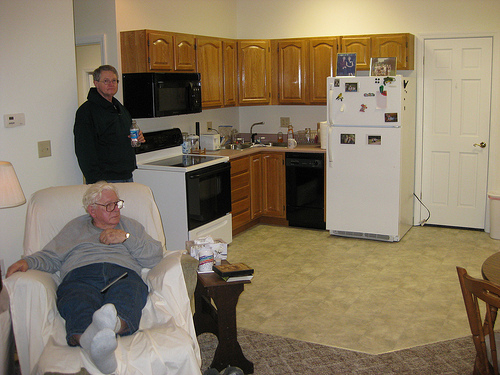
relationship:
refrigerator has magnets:
[322, 73, 416, 244] [332, 77, 402, 148]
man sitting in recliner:
[6, 181, 167, 372] [2, 181, 204, 375]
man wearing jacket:
[70, 63, 146, 180] [73, 86, 140, 181]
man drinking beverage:
[70, 63, 146, 180] [129, 119, 141, 150]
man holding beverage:
[70, 63, 146, 180] [129, 119, 141, 150]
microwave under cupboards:
[123, 72, 203, 122] [117, 30, 413, 112]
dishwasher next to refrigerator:
[281, 150, 328, 232] [322, 73, 416, 244]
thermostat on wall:
[2, 109, 28, 128] [2, 1, 84, 276]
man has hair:
[6, 181, 167, 372] [82, 181, 119, 210]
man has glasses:
[6, 181, 167, 372] [90, 200, 124, 211]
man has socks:
[6, 181, 167, 372] [74, 303, 125, 374]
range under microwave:
[133, 127, 233, 258] [123, 72, 203, 122]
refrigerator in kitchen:
[322, 73, 416, 244] [116, 2, 499, 358]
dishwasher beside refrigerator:
[281, 150, 328, 232] [322, 73, 416, 244]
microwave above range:
[123, 72, 203, 122] [133, 127, 233, 258]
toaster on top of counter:
[201, 130, 222, 154] [192, 134, 326, 156]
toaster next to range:
[201, 130, 222, 154] [133, 127, 233, 258]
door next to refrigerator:
[417, 29, 495, 232] [322, 73, 416, 244]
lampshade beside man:
[0, 158, 28, 213] [6, 181, 167, 372]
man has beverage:
[6, 181, 167, 372] [129, 119, 141, 150]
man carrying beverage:
[6, 181, 167, 372] [129, 119, 141, 150]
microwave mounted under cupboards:
[123, 72, 203, 122] [117, 30, 413, 112]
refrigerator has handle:
[322, 73, 416, 244] [325, 128, 338, 168]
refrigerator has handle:
[322, 73, 416, 244] [326, 88, 335, 128]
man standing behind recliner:
[6, 181, 167, 372] [2, 181, 204, 375]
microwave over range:
[123, 72, 203, 122] [133, 127, 233, 258]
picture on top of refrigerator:
[333, 53, 357, 77] [322, 73, 416, 244]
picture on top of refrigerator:
[368, 54, 398, 76] [322, 73, 416, 244]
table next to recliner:
[191, 254, 257, 375] [2, 181, 204, 375]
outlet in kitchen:
[205, 121, 216, 134] [116, 2, 499, 358]